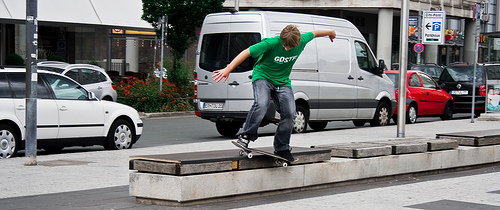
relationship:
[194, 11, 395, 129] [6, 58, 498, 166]
van on street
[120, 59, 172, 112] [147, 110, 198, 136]
flowers on road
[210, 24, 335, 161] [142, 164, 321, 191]
boy skateboarding on bench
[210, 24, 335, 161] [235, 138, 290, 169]
boy on skateboard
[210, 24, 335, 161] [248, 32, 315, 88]
boy wearing green shirt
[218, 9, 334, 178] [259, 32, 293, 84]
boy wearing shirt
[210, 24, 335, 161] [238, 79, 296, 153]
boy wearing jeans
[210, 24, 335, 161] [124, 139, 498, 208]
boy on bench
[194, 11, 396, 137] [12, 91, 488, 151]
van on street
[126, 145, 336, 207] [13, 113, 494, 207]
bench on sidewalk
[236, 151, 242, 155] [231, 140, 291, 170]
wheels on skateboard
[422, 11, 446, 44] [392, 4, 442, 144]
sign on pole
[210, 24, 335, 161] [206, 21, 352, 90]
boy extending arms